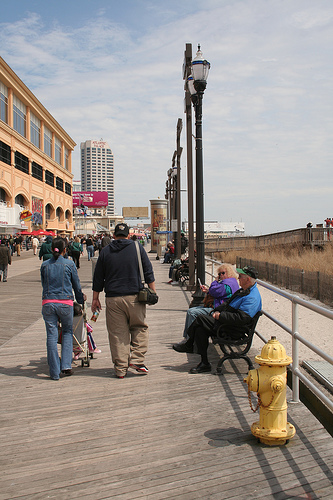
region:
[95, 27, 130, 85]
blue skiy with cascading skies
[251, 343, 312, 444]
yellow fire hydrant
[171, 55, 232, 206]
metal black street pole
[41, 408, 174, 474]
boardwalk wood planks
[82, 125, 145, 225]
tall gray building for casino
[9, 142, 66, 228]
peach colored stone building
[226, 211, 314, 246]
walkway to beach from boardwalk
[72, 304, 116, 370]
stroller with little girl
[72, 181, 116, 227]
maroon colored banner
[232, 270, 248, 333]
older man with black and blue on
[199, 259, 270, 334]
elderly couple sitting on bench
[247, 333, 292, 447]
bright yellow fire hydrant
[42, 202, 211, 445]
people walking on a board walk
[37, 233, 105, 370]
woman pushing a stroller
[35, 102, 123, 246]
two big buildings in background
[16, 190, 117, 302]
many people walking on boardwalk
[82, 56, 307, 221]
blue sky and clouds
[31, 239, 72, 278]
woman with a ponytail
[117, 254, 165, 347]
man carrying a camera bag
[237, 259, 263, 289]
elderly man in a hat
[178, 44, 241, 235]
street light on metal pole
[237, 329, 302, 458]
yellow fire extengusher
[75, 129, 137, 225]
tall hotel at a distance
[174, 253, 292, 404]
couple sitting on black bench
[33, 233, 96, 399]
woman pushing stroller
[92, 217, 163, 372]
man carrying a camera bag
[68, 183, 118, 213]
pink advertising signage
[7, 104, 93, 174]
windows in upper story building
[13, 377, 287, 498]
wooden sidewalk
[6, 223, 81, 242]
red umbrellas on city street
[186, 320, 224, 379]
Man wearing black pants.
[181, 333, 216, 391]
Man wearing black socks.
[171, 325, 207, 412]
Man wearing black shoes.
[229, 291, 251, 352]
Man wearing blue and black coat.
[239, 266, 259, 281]
Man wearing baseball hat.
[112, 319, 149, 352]
Man wearing khaki pants.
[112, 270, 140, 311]
Person wearing black shirt.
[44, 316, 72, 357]
Person wearing blue jeans.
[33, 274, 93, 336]
Person wearing pink shirt.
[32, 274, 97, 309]
Person wearing jean jacket.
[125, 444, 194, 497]
A wooden floor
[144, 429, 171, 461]
A wooden floor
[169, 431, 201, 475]
A wooden floor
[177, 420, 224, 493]
A wooden floor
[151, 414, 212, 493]
A wooden floor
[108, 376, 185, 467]
A wooden floor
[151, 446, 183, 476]
A wooden floor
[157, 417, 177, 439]
A wooden floor